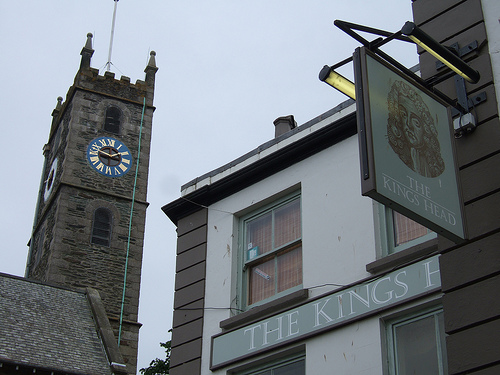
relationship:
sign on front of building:
[353, 45, 470, 245] [158, 6, 495, 374]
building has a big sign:
[158, 6, 495, 374] [353, 45, 470, 245]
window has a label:
[234, 188, 310, 316] [245, 246, 261, 263]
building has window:
[158, 6, 495, 374] [234, 188, 310, 316]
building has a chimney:
[158, 6, 495, 374] [271, 114, 297, 142]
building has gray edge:
[158, 6, 495, 374] [179, 61, 421, 198]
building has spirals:
[2, 34, 158, 373] [42, 32, 161, 111]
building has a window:
[158, 6, 495, 374] [234, 188, 310, 316]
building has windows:
[158, 6, 495, 374] [226, 140, 450, 375]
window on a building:
[234, 188, 310, 316] [158, 6, 495, 374]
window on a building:
[377, 291, 448, 375] [158, 6, 495, 374]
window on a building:
[375, 201, 438, 262] [158, 6, 495, 374]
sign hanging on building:
[353, 45, 470, 245] [158, 6, 495, 374]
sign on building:
[353, 45, 470, 245] [158, 6, 495, 374]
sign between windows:
[353, 45, 470, 245] [226, 140, 450, 375]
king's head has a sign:
[158, 6, 495, 374] [353, 45, 470, 245]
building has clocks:
[2, 34, 158, 373] [42, 135, 132, 204]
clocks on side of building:
[42, 135, 132, 204] [2, 34, 158, 373]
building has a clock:
[2, 34, 158, 373] [43, 158, 59, 201]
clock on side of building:
[83, 135, 134, 178] [2, 34, 158, 373]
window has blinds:
[234, 188, 310, 316] [246, 201, 303, 304]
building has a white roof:
[158, 6, 495, 374] [179, 61, 421, 198]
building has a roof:
[158, 6, 495, 374] [179, 61, 421, 198]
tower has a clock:
[2, 34, 158, 373] [83, 135, 134, 178]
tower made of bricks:
[2, 34, 158, 373] [71, 248, 140, 300]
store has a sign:
[157, 0, 499, 372] [353, 45, 470, 245]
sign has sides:
[353, 45, 470, 245] [353, 45, 470, 245]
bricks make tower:
[71, 248, 141, 303] [2, 34, 158, 373]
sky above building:
[162, 5, 431, 206] [158, 6, 495, 374]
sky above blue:
[162, 5, 431, 206] [168, 7, 308, 106]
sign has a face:
[353, 45, 470, 245] [396, 89, 423, 147]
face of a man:
[396, 89, 423, 147] [385, 82, 445, 176]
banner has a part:
[210, 250, 440, 369] [226, 326, 279, 360]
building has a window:
[2, 34, 158, 373] [102, 100, 122, 136]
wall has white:
[157, 0, 499, 372] [203, 129, 388, 375]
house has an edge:
[158, 6, 495, 374] [157, 180, 189, 373]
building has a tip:
[158, 6, 495, 374] [160, 194, 179, 227]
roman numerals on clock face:
[89, 137, 139, 188] [83, 135, 134, 178]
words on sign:
[242, 260, 446, 350] [210, 250, 440, 369]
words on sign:
[382, 166, 459, 228] [353, 45, 470, 245]